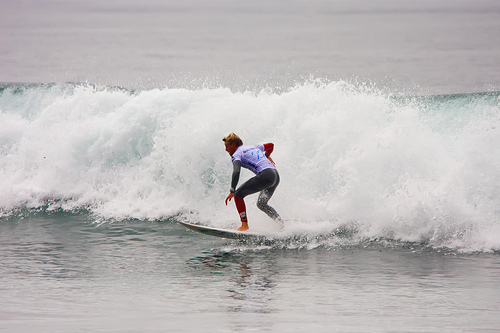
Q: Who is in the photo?
A: A man.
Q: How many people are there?
A: One.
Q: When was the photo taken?
A: Day time.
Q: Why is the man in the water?
A: Surfing.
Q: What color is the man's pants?
A: Black.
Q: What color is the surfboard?
A: White.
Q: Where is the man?
A: The water.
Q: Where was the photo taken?
A: At the ocean.